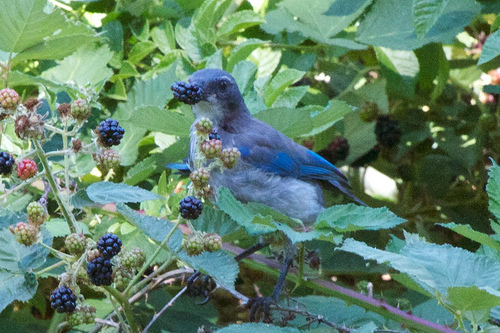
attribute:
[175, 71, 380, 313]
bird — perched, blue, black, feathered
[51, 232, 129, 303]
fruit — blue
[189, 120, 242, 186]
fruit — green, unripe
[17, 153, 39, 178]
fruit — red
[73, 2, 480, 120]
leaves — green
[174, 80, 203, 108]
fruit — blue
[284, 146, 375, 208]
wing — blue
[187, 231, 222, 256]
berries — green, red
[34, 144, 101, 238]
branch — thorny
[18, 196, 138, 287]
berries — black, ripe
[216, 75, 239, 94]
eye — black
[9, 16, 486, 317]
bush — green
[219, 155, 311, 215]
chest — feathered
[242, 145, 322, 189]
feathers — blue, gray